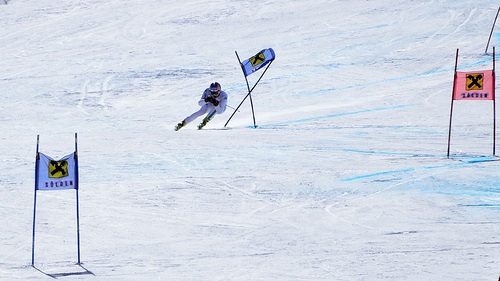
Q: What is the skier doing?
A: Rounding the blue flag.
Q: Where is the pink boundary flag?
A: In the snow.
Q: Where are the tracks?
A: In the snow.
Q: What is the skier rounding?
A: The blue flag.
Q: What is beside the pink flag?
A: Light blue lines.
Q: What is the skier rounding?
A: Blue flag.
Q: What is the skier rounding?
A: Blue flag on snow.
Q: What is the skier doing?
A: Rounding a blue flag.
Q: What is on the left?
A: Marker in the snow.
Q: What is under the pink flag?
A: Blue lines.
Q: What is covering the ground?
A: Snow.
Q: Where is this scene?
A: Snowy hill.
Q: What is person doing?
A: Skiing.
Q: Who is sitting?
A: No one.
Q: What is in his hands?
A: Poles.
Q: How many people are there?
A: One.